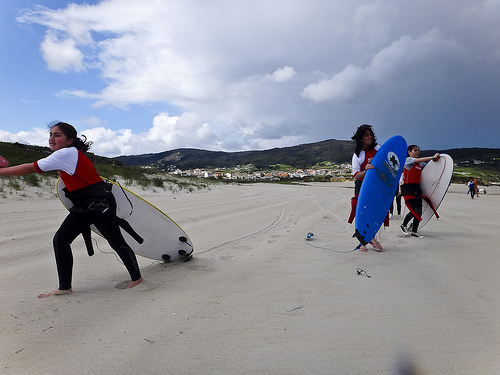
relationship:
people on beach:
[0, 118, 145, 299] [0, 176, 496, 372]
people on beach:
[401, 144, 438, 234] [0, 176, 496, 372]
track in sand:
[193, 197, 295, 256] [1, 172, 498, 373]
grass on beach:
[448, 165, 499, 186] [0, 176, 496, 372]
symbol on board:
[384, 146, 404, 173] [351, 134, 471, 251]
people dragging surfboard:
[0, 118, 145, 299] [306, 128, 416, 244]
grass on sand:
[448, 165, 499, 186] [1, 177, 500, 374]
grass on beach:
[160, 147, 362, 185] [0, 176, 496, 372]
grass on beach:
[448, 165, 499, 186] [2, 10, 497, 372]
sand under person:
[1, 172, 498, 373] [1, 117, 146, 299]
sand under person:
[1, 172, 498, 373] [347, 123, 382, 250]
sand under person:
[1, 172, 498, 373] [399, 144, 441, 241]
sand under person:
[1, 172, 498, 373] [465, 175, 479, 202]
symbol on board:
[387, 149, 401, 172] [55, 175, 194, 264]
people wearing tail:
[0, 118, 145, 299] [76, 135, 91, 152]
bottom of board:
[354, 220, 377, 243] [350, 134, 409, 247]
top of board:
[385, 131, 415, 163] [330, 129, 484, 279]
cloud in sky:
[36, 0, 438, 155] [2, 1, 497, 151]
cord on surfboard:
[301, 230, 365, 254] [350, 131, 408, 249]